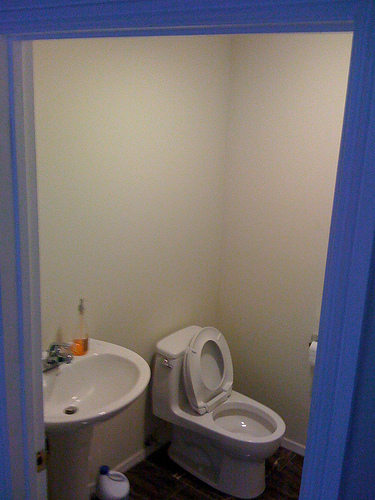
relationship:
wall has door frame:
[4, 0, 369, 497] [0, 2, 371, 496]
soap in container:
[73, 333, 88, 354] [69, 292, 92, 355]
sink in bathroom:
[45, 336, 150, 498] [0, 2, 373, 491]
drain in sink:
[63, 398, 83, 418] [45, 336, 150, 498]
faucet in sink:
[39, 342, 75, 369] [38, 337, 151, 499]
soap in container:
[73, 333, 92, 355] [71, 294, 89, 356]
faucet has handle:
[39, 342, 73, 366] [38, 351, 56, 373]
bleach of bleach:
[91, 464, 132, 500] [95, 465, 128, 497]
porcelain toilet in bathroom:
[152, 322, 286, 500] [20, 29, 356, 498]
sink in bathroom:
[38, 337, 151, 499] [20, 29, 356, 498]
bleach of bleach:
[91, 464, 132, 500] [91, 464, 132, 497]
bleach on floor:
[91, 464, 132, 500] [58, 426, 319, 497]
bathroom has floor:
[20, 29, 356, 498] [58, 426, 319, 497]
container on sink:
[71, 294, 89, 356] [23, 330, 151, 493]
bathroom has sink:
[20, 29, 356, 498] [23, 330, 151, 493]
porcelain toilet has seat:
[152, 322, 286, 500] [187, 323, 236, 415]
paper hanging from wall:
[307, 332, 321, 367] [215, 72, 362, 444]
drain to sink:
[62, 403, 79, 414] [38, 337, 151, 499]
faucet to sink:
[39, 342, 73, 366] [23, 330, 151, 493]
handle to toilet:
[157, 359, 174, 374] [158, 326, 281, 469]